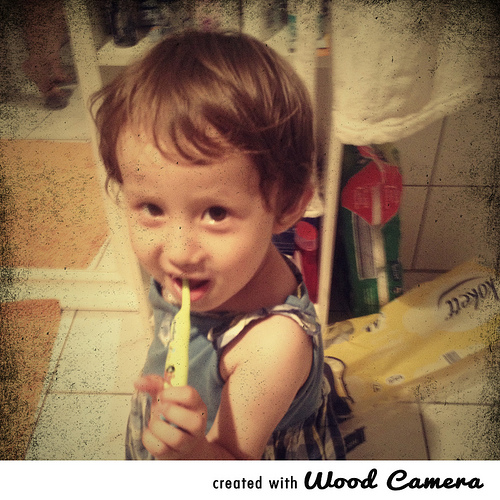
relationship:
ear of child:
[267, 150, 316, 237] [78, 64, 365, 450]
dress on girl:
[124, 256, 354, 458] [85, 32, 367, 464]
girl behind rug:
[85, 32, 367, 464] [6, 132, 123, 274]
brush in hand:
[160, 275, 191, 390] [131, 375, 208, 460]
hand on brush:
[131, 375, 208, 460] [160, 275, 191, 390]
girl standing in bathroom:
[85, 32, 367, 464] [0, 1, 499, 461]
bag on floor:
[315, 246, 498, 411] [0, 278, 499, 460]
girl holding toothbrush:
[85, 32, 367, 464] [156, 271, 213, 388]